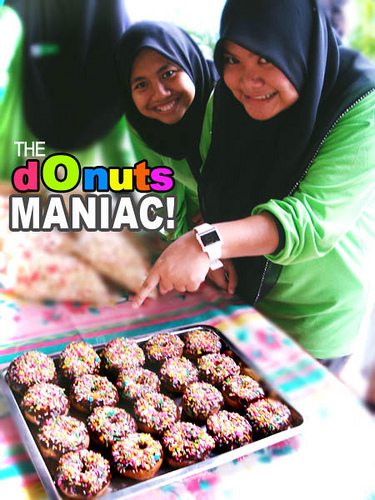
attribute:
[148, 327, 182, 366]
donuts — Pan, sprinkles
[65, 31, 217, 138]
women — smiling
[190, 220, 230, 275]
watch — white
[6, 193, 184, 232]
text print — white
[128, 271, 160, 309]
finger — pointing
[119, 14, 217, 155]
headdress — black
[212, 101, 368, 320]
top — green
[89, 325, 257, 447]
chocolate — tray , frosted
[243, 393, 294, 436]
donut — white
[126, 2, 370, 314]
woman — smiling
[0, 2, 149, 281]
person — white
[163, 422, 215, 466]
donut — white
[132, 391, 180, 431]
donut — Pan, sprinkles.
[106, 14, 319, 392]
woman — smiling, brown, Asian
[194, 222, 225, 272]
watch — white, electronic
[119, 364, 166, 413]
donut — white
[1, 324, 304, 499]
pan — donuts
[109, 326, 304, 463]
donut — white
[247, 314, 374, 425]
tablecloth — pink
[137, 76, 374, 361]
top — long sleeved, green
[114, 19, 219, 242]
person — white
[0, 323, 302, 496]
tray — silver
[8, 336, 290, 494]
donuts — Pan, sprinkles, sprinkles., sprinkled 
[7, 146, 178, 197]
text — colorful